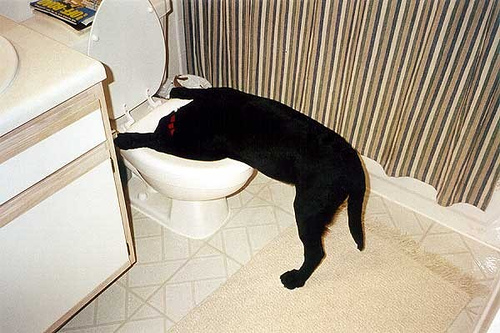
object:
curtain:
[179, 3, 494, 177]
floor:
[78, 193, 497, 333]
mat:
[204, 227, 488, 331]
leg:
[277, 184, 339, 292]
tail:
[342, 166, 372, 256]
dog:
[106, 84, 370, 286]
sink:
[0, 15, 75, 111]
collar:
[168, 113, 176, 136]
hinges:
[109, 156, 117, 175]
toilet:
[90, 3, 247, 244]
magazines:
[30, 0, 98, 26]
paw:
[113, 129, 143, 151]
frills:
[372, 232, 488, 301]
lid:
[92, 0, 172, 116]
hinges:
[119, 95, 165, 129]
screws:
[145, 88, 151, 98]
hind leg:
[279, 198, 335, 292]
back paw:
[278, 262, 308, 299]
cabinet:
[1, 118, 142, 310]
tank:
[47, 1, 174, 90]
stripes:
[392, 0, 435, 175]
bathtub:
[331, 135, 494, 252]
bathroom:
[6, 11, 499, 333]